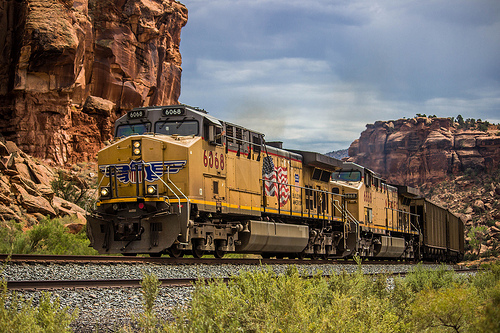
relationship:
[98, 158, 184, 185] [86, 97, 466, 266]
eagle on train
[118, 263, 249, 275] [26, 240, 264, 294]
gravel between tracks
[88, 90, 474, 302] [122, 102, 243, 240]
train has engine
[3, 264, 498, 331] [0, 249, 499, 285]
bush next to tracks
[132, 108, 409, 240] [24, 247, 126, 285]
yellow train on railroad tracks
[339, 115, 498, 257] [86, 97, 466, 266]
rock formation in back of train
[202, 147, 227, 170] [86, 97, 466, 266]
number on train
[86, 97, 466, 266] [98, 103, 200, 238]
train has front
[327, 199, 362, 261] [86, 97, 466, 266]
steps on train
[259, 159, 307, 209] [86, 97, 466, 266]
flag on train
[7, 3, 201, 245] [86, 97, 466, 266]
rock on side of train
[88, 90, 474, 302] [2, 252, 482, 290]
train on tracks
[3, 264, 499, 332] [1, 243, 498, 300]
bush on side of railroad tracks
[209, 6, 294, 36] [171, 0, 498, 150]
clouds in sky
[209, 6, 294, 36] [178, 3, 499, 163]
clouds in sky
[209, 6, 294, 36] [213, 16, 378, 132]
clouds in sky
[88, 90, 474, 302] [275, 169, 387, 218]
train has side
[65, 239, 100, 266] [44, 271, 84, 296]
railway has edge